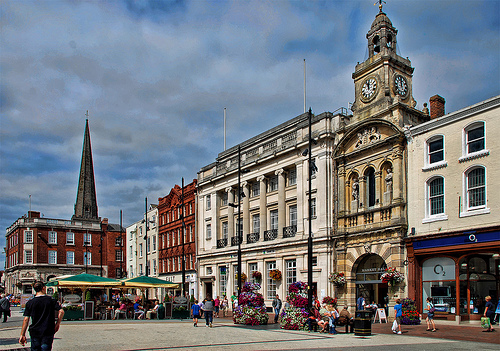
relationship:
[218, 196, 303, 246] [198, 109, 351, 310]
windows are on building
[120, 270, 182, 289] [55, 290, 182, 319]
tent over seating area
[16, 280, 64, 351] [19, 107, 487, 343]
man walking toward district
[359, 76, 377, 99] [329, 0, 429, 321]
clock on building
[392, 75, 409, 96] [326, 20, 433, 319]
clock on building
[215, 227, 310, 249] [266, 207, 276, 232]
window bars on window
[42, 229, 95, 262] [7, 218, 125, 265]
windows on building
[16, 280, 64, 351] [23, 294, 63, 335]
man wearing shirt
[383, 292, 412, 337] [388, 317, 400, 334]
person carrying bag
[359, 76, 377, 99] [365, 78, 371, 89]
clock with hands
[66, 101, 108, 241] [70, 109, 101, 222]
gray spire of a gray spire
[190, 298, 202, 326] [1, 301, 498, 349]
people on walkway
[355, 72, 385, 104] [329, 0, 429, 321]
clock on a building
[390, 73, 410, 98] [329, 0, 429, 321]
clock on a building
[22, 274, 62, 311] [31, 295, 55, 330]
man in a shirt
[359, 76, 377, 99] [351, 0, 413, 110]
clock on tower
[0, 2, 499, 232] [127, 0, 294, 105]
blue sky with clouds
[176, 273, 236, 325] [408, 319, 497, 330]
people walking on walkway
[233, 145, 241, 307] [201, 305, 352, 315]
pole on walk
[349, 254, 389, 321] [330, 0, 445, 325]
door on building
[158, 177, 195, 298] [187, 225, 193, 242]
building has window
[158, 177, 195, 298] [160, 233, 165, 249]
building has window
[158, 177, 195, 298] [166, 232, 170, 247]
building has window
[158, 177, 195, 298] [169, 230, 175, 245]
building has window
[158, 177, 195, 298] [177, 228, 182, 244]
building has window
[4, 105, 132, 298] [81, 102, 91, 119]
building has crucifix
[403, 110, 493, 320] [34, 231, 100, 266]
building made of brick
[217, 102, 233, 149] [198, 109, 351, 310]
mast on building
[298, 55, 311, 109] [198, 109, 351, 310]
mast on building